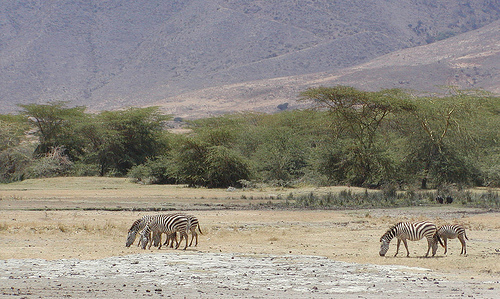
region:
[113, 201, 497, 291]
zebra's grazing on a plain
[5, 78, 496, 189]
trees with green foliage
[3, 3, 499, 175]
barren hills behind trees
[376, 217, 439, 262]
zebra with head down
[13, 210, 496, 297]
zebra's grazing on barren land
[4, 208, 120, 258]
dried vegatation in field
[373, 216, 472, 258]
group of two zebras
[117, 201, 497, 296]
two groups of zebras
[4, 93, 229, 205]
trees at edge of field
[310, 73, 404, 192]
tree and branches with green foliage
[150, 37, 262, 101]
Hills in the photo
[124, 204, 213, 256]
A group of zebra grazing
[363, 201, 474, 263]
Two zebras in the photo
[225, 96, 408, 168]
Thickets in the photo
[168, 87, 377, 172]
Trees in the photo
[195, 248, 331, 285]
Rocky fields in the photo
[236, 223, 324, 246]
Dry grass in the photo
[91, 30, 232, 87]
A hill in the background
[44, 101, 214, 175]
Trees with thorns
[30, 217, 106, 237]
Dry grass in the background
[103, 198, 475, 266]
zebras eating on a field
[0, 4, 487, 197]
mountains behind the trees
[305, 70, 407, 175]
a tree in front a mountain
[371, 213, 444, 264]
a zebra with head down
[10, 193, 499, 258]
dry grass on a field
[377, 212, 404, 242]
mane on neck of zebra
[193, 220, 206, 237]
long tail of zebra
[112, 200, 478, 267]
zebras are facing left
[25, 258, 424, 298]
little pebbles on the ground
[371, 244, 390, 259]
muzzle of zebra is black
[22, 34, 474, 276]
photograph of zebras in the wild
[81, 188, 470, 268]
zebras grazing in a field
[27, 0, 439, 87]
mountains and hills in the distance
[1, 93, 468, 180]
tall green trees towards back of field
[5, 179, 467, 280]
large field for zebras to graze in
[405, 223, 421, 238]
black and white stripes on zebra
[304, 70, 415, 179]
tall green tree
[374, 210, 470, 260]
two zebras eating grass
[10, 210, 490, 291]
brown dry field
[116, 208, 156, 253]
the zebras are eating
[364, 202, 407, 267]
the zebras are eating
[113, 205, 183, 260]
the zebras are eating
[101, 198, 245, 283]
zebras in an open field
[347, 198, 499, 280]
zebras in an open field